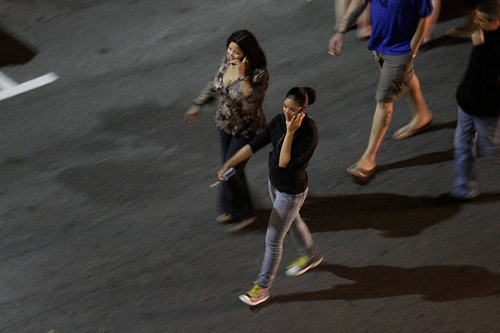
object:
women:
[209, 88, 324, 307]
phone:
[230, 53, 246, 67]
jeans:
[256, 177, 316, 286]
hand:
[218, 162, 232, 184]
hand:
[285, 112, 306, 136]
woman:
[183, 30, 269, 232]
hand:
[183, 104, 203, 124]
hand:
[230, 54, 249, 74]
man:
[327, 1, 433, 180]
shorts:
[370, 49, 417, 104]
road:
[0, 0, 499, 331]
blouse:
[193, 56, 271, 138]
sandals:
[347, 154, 379, 184]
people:
[212, 88, 325, 307]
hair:
[284, 84, 316, 106]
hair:
[226, 29, 267, 69]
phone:
[294, 107, 305, 118]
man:
[440, 4, 499, 201]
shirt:
[457, 29, 499, 118]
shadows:
[249, 259, 500, 313]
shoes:
[238, 283, 273, 306]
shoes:
[226, 214, 258, 232]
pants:
[216, 126, 256, 218]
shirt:
[367, 0, 434, 55]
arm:
[217, 113, 280, 181]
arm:
[183, 80, 216, 125]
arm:
[278, 115, 319, 169]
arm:
[230, 54, 269, 110]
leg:
[391, 74, 433, 142]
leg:
[474, 115, 499, 161]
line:
[1, 70, 60, 104]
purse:
[210, 166, 236, 189]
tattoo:
[382, 110, 392, 127]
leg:
[346, 54, 414, 183]